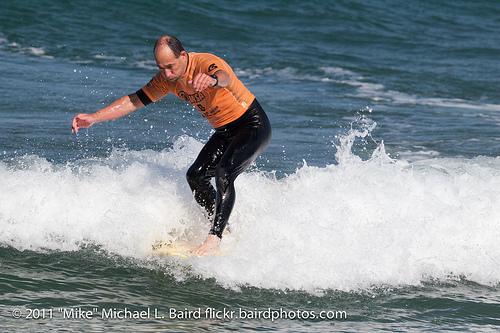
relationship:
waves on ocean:
[342, 148, 434, 249] [275, 30, 487, 157]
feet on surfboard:
[183, 230, 234, 263] [145, 207, 266, 294]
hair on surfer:
[151, 23, 186, 50] [147, 192, 301, 320]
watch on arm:
[208, 70, 221, 93] [68, 77, 154, 146]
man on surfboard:
[69, 35, 271, 255] [102, 214, 267, 263]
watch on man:
[209, 74, 219, 87] [75, 54, 282, 218]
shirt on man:
[137, 51, 262, 133] [69, 35, 271, 255]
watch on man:
[209, 74, 219, 87] [69, 35, 271, 255]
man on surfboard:
[69, 35, 271, 255] [146, 230, 215, 261]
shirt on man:
[137, 51, 262, 133] [68, 31, 276, 256]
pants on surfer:
[183, 98, 273, 239] [69, 34, 271, 256]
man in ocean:
[69, 35, 271, 255] [3, 2, 496, 329]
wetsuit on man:
[187, 109, 274, 256] [68, 31, 276, 256]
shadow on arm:
[108, 84, 185, 128] [59, 79, 164, 129]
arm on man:
[59, 79, 164, 129] [136, 30, 330, 214]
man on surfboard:
[68, 31, 276, 256] [151, 231, 236, 263]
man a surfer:
[68, 31, 276, 256] [69, 34, 271, 256]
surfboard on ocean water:
[125, 214, 242, 282] [7, 134, 497, 333]